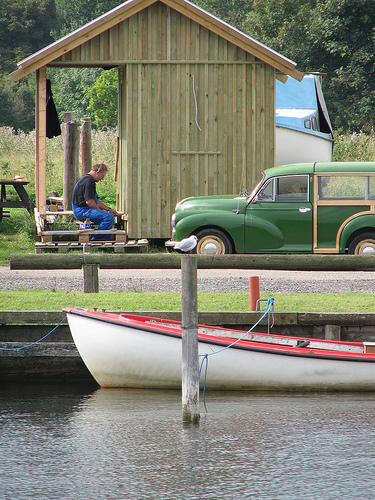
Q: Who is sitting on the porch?
A: Man.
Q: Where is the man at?
A: Porch.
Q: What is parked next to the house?
A: Car.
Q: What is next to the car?
A: House.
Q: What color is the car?
A: Green.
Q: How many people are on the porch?
A: One.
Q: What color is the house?
A: Brown.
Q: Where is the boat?
A: Water.